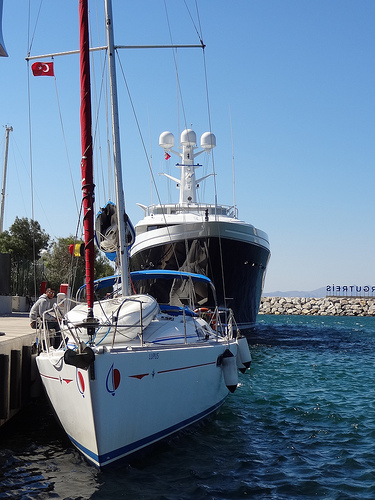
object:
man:
[29, 286, 62, 335]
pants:
[38, 321, 61, 336]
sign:
[324, 281, 375, 298]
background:
[259, 274, 372, 321]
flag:
[31, 61, 55, 79]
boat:
[35, 265, 251, 469]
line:
[115, 51, 182, 287]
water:
[0, 315, 375, 500]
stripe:
[128, 361, 215, 380]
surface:
[0, 310, 34, 345]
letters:
[349, 285, 354, 291]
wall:
[259, 296, 375, 317]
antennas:
[158, 128, 177, 150]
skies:
[0, 0, 375, 293]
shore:
[260, 287, 375, 318]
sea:
[0, 315, 375, 500]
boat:
[124, 128, 271, 323]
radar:
[157, 130, 217, 204]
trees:
[7, 215, 50, 295]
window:
[152, 207, 176, 216]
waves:
[233, 454, 262, 474]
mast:
[77, 0, 98, 326]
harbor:
[0, 268, 375, 500]